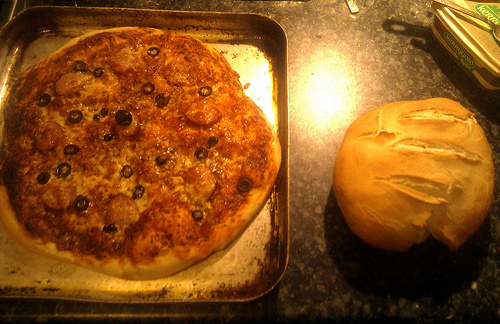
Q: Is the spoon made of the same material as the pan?
A: Yes, both the spoon and the pan are made of metal.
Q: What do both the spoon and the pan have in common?
A: The material, both the spoon and the pan are metallic.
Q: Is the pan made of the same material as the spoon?
A: Yes, both the pan and the spoon are made of metal.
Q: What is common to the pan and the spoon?
A: The material, both the pan and the spoon are metallic.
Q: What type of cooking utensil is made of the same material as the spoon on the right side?
A: The pan is made of the same material as the spoon.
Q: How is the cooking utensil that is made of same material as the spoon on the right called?
A: The cooking utensil is a pan.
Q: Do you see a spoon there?
A: Yes, there is a spoon.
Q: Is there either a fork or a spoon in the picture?
A: Yes, there is a spoon.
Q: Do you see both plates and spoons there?
A: No, there is a spoon but no plates.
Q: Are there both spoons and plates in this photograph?
A: No, there is a spoon but no plates.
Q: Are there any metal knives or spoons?
A: Yes, there is a metal spoon.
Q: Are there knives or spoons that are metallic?
A: Yes, the spoon is metallic.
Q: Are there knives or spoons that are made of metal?
A: Yes, the spoon is made of metal.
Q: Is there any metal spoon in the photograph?
A: Yes, there is a metal spoon.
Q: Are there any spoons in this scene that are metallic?
A: Yes, there is a spoon that is metallic.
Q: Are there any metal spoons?
A: Yes, there is a spoon that is made of metal.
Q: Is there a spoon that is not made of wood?
A: Yes, there is a spoon that is made of metal.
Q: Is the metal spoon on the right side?
A: Yes, the spoon is on the right of the image.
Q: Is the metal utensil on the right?
A: Yes, the spoon is on the right of the image.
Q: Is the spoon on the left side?
A: No, the spoon is on the right of the image.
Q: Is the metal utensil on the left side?
A: No, the spoon is on the right of the image.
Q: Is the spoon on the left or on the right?
A: The spoon is on the right of the image.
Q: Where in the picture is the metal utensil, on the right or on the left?
A: The spoon is on the right of the image.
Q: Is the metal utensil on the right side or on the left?
A: The spoon is on the right of the image.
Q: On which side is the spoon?
A: The spoon is on the right of the image.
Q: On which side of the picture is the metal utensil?
A: The spoon is on the right of the image.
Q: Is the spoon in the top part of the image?
A: Yes, the spoon is in the top of the image.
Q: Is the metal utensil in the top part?
A: Yes, the spoon is in the top of the image.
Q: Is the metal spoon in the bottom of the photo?
A: No, the spoon is in the top of the image.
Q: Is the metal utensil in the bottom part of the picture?
A: No, the spoon is in the top of the image.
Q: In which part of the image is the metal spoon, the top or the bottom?
A: The spoon is in the top of the image.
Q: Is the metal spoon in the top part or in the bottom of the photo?
A: The spoon is in the top of the image.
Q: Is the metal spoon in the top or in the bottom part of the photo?
A: The spoon is in the top of the image.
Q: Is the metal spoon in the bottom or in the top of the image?
A: The spoon is in the top of the image.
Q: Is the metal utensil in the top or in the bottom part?
A: The spoon is in the top of the image.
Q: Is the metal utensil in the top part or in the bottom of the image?
A: The spoon is in the top of the image.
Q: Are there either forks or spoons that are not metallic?
A: No, there is a spoon but it is metallic.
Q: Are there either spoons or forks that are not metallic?
A: No, there is a spoon but it is metallic.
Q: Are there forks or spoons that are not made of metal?
A: No, there is a spoon but it is made of metal.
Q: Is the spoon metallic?
A: Yes, the spoon is metallic.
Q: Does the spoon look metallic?
A: Yes, the spoon is metallic.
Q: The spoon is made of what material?
A: The spoon is made of metal.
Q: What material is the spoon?
A: The spoon is made of metal.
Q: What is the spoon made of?
A: The spoon is made of metal.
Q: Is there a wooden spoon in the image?
A: No, there is a spoon but it is metallic.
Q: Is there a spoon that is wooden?
A: No, there is a spoon but it is metallic.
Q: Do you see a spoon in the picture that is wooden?
A: No, there is a spoon but it is metallic.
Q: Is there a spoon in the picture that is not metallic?
A: No, there is a spoon but it is metallic.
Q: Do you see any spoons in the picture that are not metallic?
A: No, there is a spoon but it is metallic.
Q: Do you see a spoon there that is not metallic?
A: No, there is a spoon but it is metallic.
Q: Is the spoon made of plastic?
A: No, the spoon is made of metal.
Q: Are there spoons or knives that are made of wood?
A: No, there is a spoon but it is made of metal.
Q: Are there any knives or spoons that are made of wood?
A: No, there is a spoon but it is made of metal.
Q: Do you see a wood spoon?
A: No, there is a spoon but it is made of metal.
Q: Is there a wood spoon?
A: No, there is a spoon but it is made of metal.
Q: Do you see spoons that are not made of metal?
A: No, there is a spoon but it is made of metal.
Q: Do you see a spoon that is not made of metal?
A: No, there is a spoon but it is made of metal.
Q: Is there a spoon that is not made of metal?
A: No, there is a spoon but it is made of metal.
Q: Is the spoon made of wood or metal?
A: The spoon is made of metal.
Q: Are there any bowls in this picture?
A: No, there are no bowls.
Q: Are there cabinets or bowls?
A: No, there are no bowls or cabinets.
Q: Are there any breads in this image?
A: Yes, there is a bread.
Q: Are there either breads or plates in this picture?
A: Yes, there is a bread.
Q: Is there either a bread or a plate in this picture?
A: Yes, there is a bread.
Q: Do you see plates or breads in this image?
A: Yes, there is a bread.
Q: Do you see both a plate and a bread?
A: No, there is a bread but no plates.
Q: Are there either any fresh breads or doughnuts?
A: Yes, there is a fresh bread.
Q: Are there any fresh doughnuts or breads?
A: Yes, there is a fresh bread.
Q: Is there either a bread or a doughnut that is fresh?
A: Yes, the bread is fresh.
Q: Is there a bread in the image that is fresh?
A: Yes, there is a fresh bread.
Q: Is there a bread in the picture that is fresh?
A: Yes, there is a bread that is fresh.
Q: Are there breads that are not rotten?
A: Yes, there is a fresh bread.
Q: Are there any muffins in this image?
A: No, there are no muffins.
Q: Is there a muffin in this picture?
A: No, there are no muffins.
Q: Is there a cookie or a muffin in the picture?
A: No, there are no muffins or cookies.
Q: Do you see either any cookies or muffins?
A: No, there are no muffins or cookies.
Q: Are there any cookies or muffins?
A: No, there are no muffins or cookies.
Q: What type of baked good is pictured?
A: The baked good is a bread.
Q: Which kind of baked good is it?
A: The food is a bread.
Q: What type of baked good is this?
A: This is a bread.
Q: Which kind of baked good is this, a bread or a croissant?
A: This is a bread.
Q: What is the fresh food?
A: The food is a bread.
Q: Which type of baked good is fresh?
A: The baked good is a bread.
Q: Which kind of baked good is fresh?
A: The baked good is a bread.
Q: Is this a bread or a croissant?
A: This is a bread.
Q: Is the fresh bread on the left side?
A: No, the bread is on the right of the image.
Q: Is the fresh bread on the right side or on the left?
A: The bread is on the right of the image.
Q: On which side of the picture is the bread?
A: The bread is on the right of the image.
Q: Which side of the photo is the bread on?
A: The bread is on the right of the image.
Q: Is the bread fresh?
A: Yes, the bread is fresh.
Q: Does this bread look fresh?
A: Yes, the bread is fresh.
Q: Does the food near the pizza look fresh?
A: Yes, the bread is fresh.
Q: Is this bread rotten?
A: No, the bread is fresh.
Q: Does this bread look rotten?
A: No, the bread is fresh.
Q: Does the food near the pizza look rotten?
A: No, the bread is fresh.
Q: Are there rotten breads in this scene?
A: No, there is a bread but it is fresh.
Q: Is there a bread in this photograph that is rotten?
A: No, there is a bread but it is fresh.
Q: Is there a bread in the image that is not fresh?
A: No, there is a bread but it is fresh.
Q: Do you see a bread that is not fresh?
A: No, there is a bread but it is fresh.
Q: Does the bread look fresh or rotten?
A: The bread is fresh.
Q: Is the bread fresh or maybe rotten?
A: The bread is fresh.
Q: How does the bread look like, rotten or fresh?
A: The bread is fresh.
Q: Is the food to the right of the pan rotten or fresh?
A: The bread is fresh.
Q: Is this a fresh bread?
A: Yes, this is a fresh bread.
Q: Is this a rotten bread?
A: No, this is a fresh bread.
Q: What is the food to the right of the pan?
A: The food is a bread.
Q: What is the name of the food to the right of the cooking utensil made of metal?
A: The food is a bread.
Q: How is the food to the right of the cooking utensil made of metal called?
A: The food is a bread.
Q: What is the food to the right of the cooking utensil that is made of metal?
A: The food is a bread.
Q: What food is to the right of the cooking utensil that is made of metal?
A: The food is a bread.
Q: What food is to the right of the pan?
A: The food is a bread.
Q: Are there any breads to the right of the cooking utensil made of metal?
A: Yes, there is a bread to the right of the pan.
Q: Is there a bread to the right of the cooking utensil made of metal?
A: Yes, there is a bread to the right of the pan.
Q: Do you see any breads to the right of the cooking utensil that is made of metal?
A: Yes, there is a bread to the right of the pan.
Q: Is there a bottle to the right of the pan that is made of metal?
A: No, there is a bread to the right of the pan.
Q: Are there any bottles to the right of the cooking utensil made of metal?
A: No, there is a bread to the right of the pan.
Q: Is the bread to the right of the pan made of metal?
A: Yes, the bread is to the right of the pan.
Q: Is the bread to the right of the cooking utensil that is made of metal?
A: Yes, the bread is to the right of the pan.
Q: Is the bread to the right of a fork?
A: No, the bread is to the right of the pan.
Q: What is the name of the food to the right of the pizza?
A: The food is a bread.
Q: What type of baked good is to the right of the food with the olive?
A: The food is a bread.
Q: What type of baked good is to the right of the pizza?
A: The food is a bread.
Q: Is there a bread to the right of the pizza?
A: Yes, there is a bread to the right of the pizza.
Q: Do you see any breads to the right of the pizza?
A: Yes, there is a bread to the right of the pizza.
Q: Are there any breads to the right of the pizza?
A: Yes, there is a bread to the right of the pizza.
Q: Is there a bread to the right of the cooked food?
A: Yes, there is a bread to the right of the pizza.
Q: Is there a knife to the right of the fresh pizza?
A: No, there is a bread to the right of the pizza.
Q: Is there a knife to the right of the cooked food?
A: No, there is a bread to the right of the pizza.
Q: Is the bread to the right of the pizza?
A: Yes, the bread is to the right of the pizza.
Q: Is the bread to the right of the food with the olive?
A: Yes, the bread is to the right of the pizza.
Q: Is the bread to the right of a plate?
A: No, the bread is to the right of the pizza.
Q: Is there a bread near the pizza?
A: Yes, there is a bread near the pizza.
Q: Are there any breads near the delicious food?
A: Yes, there is a bread near the pizza.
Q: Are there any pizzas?
A: Yes, there is a pizza.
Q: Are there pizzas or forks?
A: Yes, there is a pizza.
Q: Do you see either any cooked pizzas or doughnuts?
A: Yes, there is a cooked pizza.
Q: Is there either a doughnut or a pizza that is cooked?
A: Yes, the pizza is cooked.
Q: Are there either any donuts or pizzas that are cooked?
A: Yes, the pizza is cooked.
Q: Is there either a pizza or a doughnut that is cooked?
A: Yes, the pizza is cooked.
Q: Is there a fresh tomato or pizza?
A: Yes, there is a fresh pizza.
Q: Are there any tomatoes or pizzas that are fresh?
A: Yes, the pizza is fresh.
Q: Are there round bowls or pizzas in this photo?
A: Yes, there is a round pizza.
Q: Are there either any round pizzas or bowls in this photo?
A: Yes, there is a round pizza.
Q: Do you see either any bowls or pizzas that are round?
A: Yes, the pizza is round.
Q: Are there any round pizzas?
A: Yes, there is a round pizza.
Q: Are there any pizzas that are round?
A: Yes, there is a pizza that is round.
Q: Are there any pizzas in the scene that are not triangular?
A: Yes, there is a round pizza.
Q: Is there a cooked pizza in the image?
A: Yes, there is a cooked pizza.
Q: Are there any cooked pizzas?
A: Yes, there is a cooked pizza.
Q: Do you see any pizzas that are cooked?
A: Yes, there is a cooked pizza.